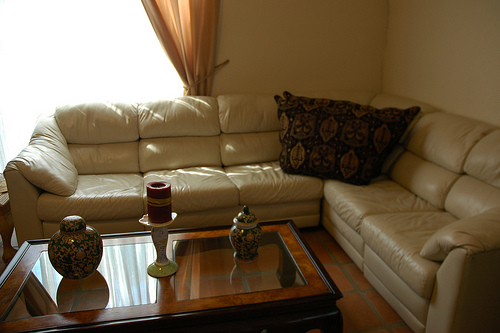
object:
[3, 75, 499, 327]
sectional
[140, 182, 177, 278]
candle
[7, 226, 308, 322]
top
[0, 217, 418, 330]
flooring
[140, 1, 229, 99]
curtain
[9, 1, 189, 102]
window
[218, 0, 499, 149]
wall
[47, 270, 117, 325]
reflection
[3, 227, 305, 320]
glass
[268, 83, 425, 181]
cushion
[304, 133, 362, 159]
pattern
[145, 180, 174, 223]
candle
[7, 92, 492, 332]
couch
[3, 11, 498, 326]
living room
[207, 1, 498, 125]
walls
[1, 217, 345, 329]
coffee table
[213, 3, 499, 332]
corner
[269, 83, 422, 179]
corner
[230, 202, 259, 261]
pot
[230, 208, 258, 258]
design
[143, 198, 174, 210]
design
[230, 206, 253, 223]
lid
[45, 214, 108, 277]
decorations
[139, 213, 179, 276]
candelabra